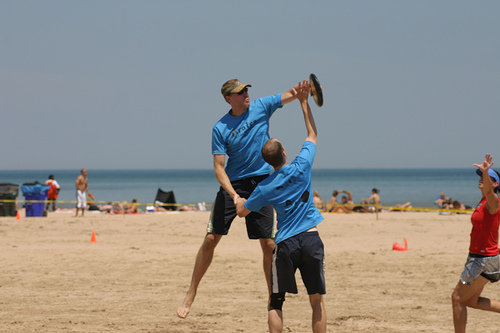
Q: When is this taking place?
A: Daytime.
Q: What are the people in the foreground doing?
A: Playing frisbee.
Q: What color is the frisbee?
A: Black.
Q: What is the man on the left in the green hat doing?
A: Jumping.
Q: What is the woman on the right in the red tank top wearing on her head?
A: Visor.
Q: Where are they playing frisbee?
A: Sand.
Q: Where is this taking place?
A: At the beach.